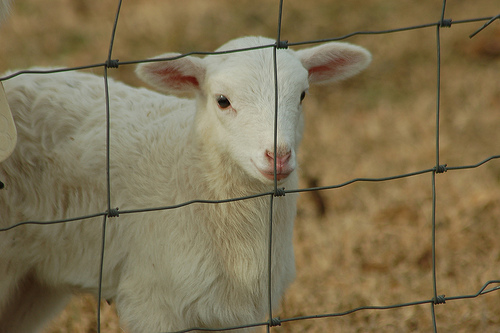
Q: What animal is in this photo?
A: A sheep.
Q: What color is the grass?
A: Brown.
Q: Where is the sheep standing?
A: In a fenced enclosure.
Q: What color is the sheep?
A: White.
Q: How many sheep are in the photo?
A: 1.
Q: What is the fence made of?
A: Wire.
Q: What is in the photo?
A: A white animal.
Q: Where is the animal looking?
A: Outside the pen.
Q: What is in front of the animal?
A: A fence.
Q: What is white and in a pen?
A: The animal.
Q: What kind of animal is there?
A: A baby animal.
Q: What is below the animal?
A: The ground.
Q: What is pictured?
A: A baby lamb.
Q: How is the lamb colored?
A: White with a pink nose.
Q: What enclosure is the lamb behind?
A: Metal fence.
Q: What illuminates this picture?
A: Natural sunlight.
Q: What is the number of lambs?
A: One.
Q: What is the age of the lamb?
A: Young.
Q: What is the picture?
A: Lamb.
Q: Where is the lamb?
A: Behind the fence.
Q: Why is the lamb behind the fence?
A: To stay in.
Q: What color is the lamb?
A: White.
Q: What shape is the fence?
A: Square.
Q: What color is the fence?
A: Gray.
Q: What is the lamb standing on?
A: Grass.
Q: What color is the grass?
A: Brown.